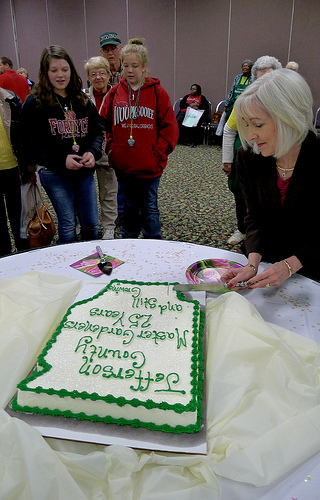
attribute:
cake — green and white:
[7, 278, 233, 441]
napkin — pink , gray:
[57, 234, 121, 278]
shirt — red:
[107, 81, 174, 174]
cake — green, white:
[1, 277, 209, 454]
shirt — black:
[15, 88, 105, 170]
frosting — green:
[9, 276, 207, 434]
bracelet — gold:
[281, 259, 291, 276]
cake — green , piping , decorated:
[55, 267, 196, 328]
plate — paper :
[154, 234, 259, 312]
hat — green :
[99, 29, 122, 45]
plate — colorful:
[185, 257, 256, 292]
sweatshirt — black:
[22, 91, 107, 167]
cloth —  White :
[122, 233, 187, 282]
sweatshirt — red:
[97, 75, 178, 175]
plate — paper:
[185, 257, 249, 291]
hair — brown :
[32, 43, 96, 112]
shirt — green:
[227, 70, 257, 116]